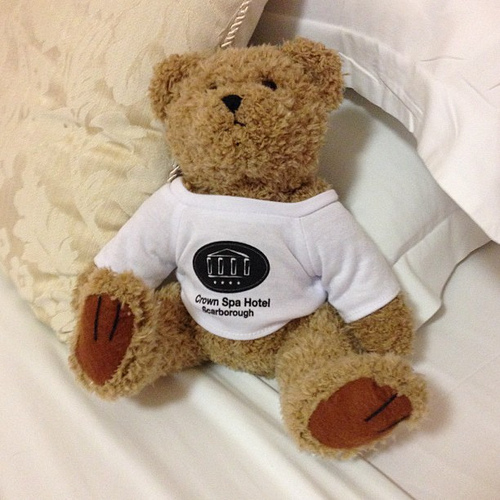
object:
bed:
[0, 0, 498, 500]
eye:
[205, 81, 218, 92]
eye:
[259, 78, 277, 92]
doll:
[66, 37, 433, 462]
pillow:
[0, 0, 272, 347]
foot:
[61, 274, 158, 396]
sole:
[308, 377, 411, 448]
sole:
[74, 293, 135, 385]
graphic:
[192, 240, 270, 319]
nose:
[220, 93, 242, 110]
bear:
[69, 36, 428, 462]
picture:
[193, 241, 271, 293]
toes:
[109, 302, 134, 344]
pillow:
[318, 88, 491, 334]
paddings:
[305, 372, 412, 459]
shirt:
[91, 177, 399, 341]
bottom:
[73, 291, 134, 387]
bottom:
[308, 374, 412, 452]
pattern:
[32, 86, 98, 226]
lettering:
[195, 294, 270, 319]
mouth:
[222, 119, 247, 131]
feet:
[292, 357, 426, 465]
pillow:
[257, 7, 499, 248]